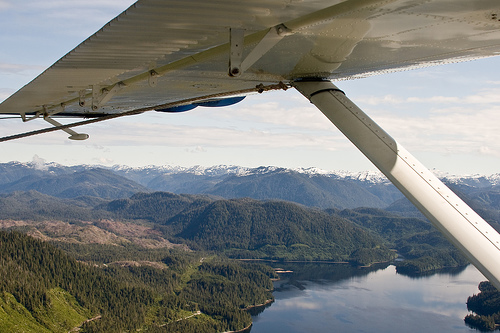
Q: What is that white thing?
A: Airplane wing.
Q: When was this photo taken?
A: Daylight.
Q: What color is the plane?
A: White.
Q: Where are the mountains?
A: In the distance.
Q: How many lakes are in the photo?
A: 1.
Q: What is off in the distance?
A: Snow covered mountains.